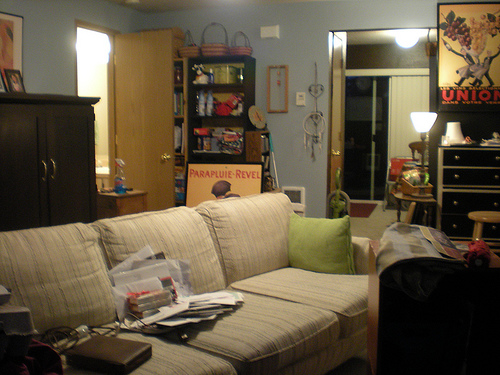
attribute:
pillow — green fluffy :
[286, 211, 356, 275]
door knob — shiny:
[157, 150, 174, 165]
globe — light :
[393, 37, 418, 47]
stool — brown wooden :
[466, 207, 498, 237]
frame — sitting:
[3, 65, 26, 93]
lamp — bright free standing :
[403, 94, 443, 204]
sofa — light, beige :
[2, 189, 377, 374]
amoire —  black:
[0, 92, 101, 233]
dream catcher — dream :
[299, 58, 325, 168]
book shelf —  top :
[186, 59, 251, 174]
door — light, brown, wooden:
[109, 28, 179, 213]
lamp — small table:
[408, 108, 440, 198]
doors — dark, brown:
[0, 87, 102, 249]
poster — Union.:
[433, 3, 499, 105]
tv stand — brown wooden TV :
[7, 90, 116, 232]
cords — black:
[47, 319, 189, 344]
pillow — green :
[288, 207, 355, 271]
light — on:
[74, 27, 111, 64]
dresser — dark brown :
[3, 91, 107, 233]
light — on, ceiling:
[381, 21, 430, 53]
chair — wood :
[464, 203, 499, 245]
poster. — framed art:
[432, 4, 493, 105]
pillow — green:
[284, 202, 362, 277]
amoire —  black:
[0, 78, 133, 243]